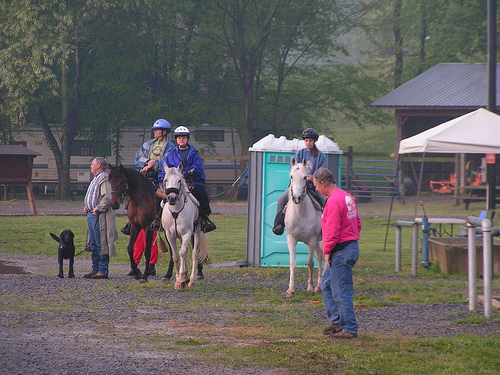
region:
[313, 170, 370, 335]
man wearing jeans and a red shirt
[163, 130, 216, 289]
woman with a blue jacket riding a white horse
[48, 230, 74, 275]
black dog standing outside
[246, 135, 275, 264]
outdoor portapotty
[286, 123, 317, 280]
girl with a black helmet riding a white horse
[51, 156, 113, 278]
man with a brown jacket walking a dog on a leash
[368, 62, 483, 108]
roof on a building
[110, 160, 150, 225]
brown horse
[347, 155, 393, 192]
metal fence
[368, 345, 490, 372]
patch of green grass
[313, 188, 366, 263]
pink and orange shirt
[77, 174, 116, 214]
blue shirt with white stripes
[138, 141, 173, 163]
tan shirt with logo on front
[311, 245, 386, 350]
pair of blue jeans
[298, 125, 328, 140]
blue and black helmet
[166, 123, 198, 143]
white helmet with holes in the front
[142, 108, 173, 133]
shiny blue helmet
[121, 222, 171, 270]
red fabric on horse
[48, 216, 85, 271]
shiny black coat on dog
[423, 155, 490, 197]
orange equipment in the shed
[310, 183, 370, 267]
a red shirt on man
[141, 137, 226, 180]
a blue jacket on man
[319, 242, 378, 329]
a pair of jeans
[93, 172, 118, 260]
a long trench coat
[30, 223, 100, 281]
a black dog on leash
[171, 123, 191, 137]
a white hemlet on head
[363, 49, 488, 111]
the edge of a metal roof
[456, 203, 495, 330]
two metal poles in ground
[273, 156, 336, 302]
a white horse at park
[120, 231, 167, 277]
a pair of red pants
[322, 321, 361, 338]
Man is wearing shoes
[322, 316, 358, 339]
Man is wearing brown shoes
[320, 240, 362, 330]
Man is wearing pants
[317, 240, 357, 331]
Man is wearing jeans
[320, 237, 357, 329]
Man is wearing blue jeans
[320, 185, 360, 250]
Man is wearing a sweatshirt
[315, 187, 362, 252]
Man is wearing a pink sweatshirt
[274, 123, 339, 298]
Girl is riding a horse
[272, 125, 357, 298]
Girl is riding a white horse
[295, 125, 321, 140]
Girl is wearing a helmet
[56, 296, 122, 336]
gray gravel on ground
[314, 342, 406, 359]
patch of grass on the ground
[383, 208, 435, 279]
small silver railing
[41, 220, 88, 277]
small black dot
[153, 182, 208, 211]
black fabric around horse's face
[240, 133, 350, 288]
blue and gray porta pottie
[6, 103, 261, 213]
white trailer in the background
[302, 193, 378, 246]
pink and white shirt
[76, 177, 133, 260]
man wearing long trench coat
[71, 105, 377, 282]
riders on back of horses